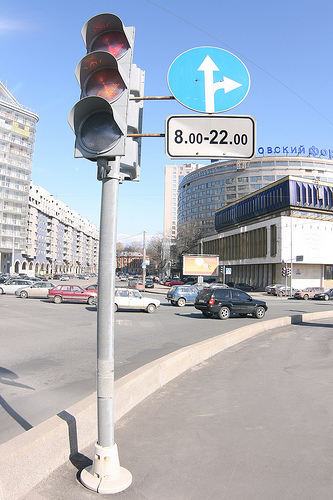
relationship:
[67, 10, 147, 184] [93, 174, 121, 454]
traffic light on pole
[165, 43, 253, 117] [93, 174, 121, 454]
sign board on pole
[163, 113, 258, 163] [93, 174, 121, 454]
sign board on pole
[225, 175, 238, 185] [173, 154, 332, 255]
window on building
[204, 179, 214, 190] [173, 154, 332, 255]
window on building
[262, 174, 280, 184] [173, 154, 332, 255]
window on building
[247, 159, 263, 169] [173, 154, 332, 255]
window on building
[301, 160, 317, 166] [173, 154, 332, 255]
window on building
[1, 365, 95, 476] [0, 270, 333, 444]
shadow on parking lot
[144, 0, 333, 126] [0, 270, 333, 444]
power line over parking lot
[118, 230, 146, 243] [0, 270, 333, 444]
power line over parking lot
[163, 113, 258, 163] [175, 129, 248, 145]
sign board shows times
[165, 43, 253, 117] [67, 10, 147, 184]
sign board next to traffic light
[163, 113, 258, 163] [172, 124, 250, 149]
sign board lists times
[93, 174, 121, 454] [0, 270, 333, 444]
pole in parking lot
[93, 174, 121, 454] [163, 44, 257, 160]
pole holding up traffic information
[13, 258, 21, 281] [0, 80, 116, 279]
arch in a building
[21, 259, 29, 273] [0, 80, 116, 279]
arch in a building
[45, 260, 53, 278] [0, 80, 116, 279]
arch in a building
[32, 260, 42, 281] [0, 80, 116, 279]
arch in a building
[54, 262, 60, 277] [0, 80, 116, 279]
arch in a building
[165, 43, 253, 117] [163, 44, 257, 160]
sign board for traffic information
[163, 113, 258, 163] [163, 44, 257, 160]
sign board for traffic information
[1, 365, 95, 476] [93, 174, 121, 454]
shadow of pole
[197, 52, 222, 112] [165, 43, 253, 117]
arrow on sign board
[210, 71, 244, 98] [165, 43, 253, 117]
arrow on sign board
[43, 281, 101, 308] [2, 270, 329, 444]
car in parking lot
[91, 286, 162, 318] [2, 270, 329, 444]
car in parking lot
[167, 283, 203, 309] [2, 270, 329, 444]
car in parking lot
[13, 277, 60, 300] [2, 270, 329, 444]
car in parking lot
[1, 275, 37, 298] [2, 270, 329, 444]
car in parking lot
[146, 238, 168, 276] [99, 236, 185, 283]
tree in distance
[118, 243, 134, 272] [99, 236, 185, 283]
tree in distance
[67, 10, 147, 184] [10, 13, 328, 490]
traffic light in foreground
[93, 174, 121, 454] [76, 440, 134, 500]
pole has a base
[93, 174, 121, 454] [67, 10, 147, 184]
pole for traffic light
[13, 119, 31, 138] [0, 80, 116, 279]
balcony on building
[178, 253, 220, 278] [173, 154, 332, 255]
billboard next to a building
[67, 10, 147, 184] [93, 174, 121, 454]
traffic light on a pole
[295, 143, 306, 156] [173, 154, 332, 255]
letter on top of building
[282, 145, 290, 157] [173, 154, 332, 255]
letter on top of building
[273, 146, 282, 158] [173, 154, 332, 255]
letter on top of building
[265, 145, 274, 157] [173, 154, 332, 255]
letter on top of building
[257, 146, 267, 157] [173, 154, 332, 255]
letter on top of building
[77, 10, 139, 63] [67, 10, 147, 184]
light part of traffic light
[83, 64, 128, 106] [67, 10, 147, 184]
light part of traffic light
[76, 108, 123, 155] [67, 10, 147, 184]
light part of traffic light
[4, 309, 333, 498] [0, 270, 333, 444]
curve in parking lot